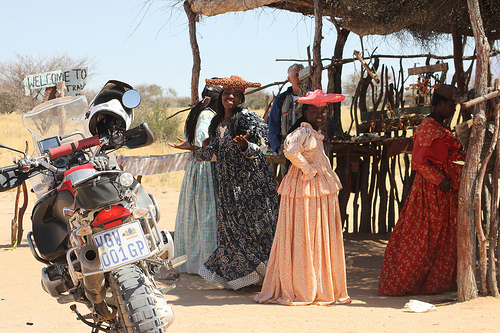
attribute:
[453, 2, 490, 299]
post — wooden, gnarled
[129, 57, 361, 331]
women — smiling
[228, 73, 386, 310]
dress — orange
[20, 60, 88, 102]
sign — black and white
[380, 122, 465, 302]
dress — long, peach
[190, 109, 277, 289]
dress — black and white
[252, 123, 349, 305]
dress — peach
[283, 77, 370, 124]
hat — red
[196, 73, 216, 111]
ribbon — pink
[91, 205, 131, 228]
tailight — red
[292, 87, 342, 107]
hat — pink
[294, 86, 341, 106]
hat — red